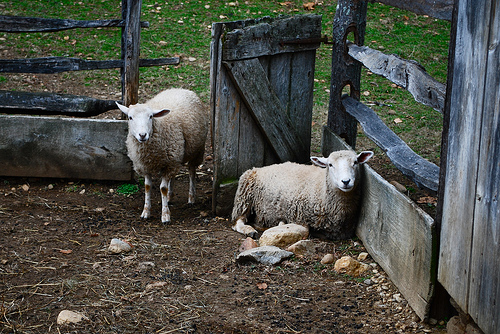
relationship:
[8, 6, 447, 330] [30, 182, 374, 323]
pen of plants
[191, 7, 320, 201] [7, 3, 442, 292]
door of pen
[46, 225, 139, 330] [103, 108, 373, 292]
rocks next to sheep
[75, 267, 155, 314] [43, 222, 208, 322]
straw on ground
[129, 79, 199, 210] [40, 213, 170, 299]
sheep in dirt